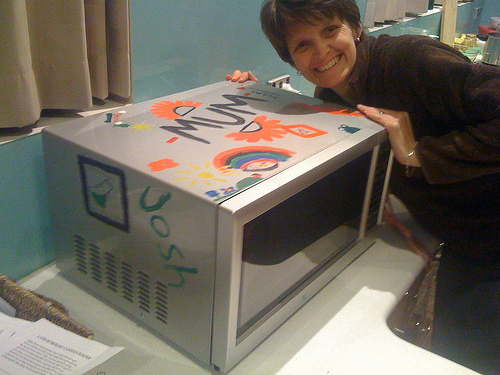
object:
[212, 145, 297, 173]
rainbow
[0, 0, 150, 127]
curtain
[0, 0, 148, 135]
window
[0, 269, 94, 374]
basket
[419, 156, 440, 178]
ground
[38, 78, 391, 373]
microwave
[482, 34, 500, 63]
crockpot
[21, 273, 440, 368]
table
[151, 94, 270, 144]
art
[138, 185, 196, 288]
art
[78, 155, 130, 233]
art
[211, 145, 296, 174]
art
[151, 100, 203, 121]
art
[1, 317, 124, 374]
paper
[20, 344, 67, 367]
text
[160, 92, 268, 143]
mum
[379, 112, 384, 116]
ring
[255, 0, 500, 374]
woman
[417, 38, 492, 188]
sweater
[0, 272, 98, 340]
wicker basket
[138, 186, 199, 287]
josh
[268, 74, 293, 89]
outlet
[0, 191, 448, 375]
counter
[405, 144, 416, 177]
bracelet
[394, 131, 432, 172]
wrist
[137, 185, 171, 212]
paint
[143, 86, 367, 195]
drawings